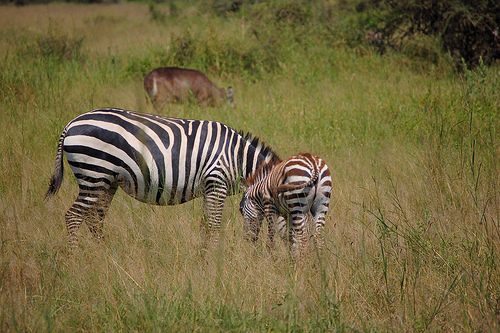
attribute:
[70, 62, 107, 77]
bush — green, growing, part, edge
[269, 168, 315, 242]
zebra — small, large, standing, back, part, bulky, striped, pair, baby, mother, grazing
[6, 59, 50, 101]
grass — tall, part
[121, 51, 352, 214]
animals — grazing, standing, wild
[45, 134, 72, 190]
tail — long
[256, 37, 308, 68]
field — grass, grassy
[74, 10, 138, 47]
plain — part